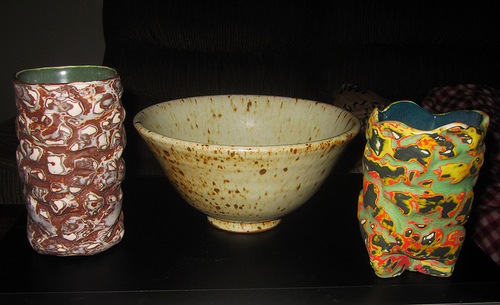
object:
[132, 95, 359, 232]
bowl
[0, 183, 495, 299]
table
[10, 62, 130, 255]
pattern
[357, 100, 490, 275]
pot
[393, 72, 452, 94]
chair